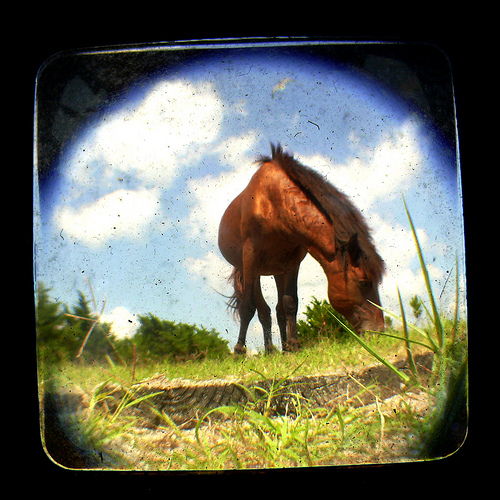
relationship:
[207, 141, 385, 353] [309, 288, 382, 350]
horse has jaw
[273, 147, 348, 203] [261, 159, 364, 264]
hair along neck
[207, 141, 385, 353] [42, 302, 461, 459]
horse standing on grass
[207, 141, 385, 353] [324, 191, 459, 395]
horse in grass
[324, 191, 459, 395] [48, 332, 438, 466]
grass in field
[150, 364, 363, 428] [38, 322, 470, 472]
wooden edging on grass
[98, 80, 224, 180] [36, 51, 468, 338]
clouds in sky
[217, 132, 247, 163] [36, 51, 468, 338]
clouds in sky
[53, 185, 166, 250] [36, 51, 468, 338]
clouds in sky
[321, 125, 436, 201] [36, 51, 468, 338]
clouds in sky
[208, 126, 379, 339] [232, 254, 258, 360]
horse has leg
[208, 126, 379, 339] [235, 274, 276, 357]
horse has leg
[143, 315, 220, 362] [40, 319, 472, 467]
green bush in field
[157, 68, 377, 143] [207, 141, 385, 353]
sky behind horse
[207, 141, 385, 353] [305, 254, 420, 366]
horse has head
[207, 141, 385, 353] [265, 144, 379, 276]
horse has mane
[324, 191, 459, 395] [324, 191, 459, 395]
grass are in grass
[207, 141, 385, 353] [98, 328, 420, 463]
horse grazing in grass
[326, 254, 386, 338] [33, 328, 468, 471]
head down to ground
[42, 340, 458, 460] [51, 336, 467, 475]
grass on ground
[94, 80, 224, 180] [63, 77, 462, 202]
clouds in sky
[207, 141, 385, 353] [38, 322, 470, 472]
horse eating grass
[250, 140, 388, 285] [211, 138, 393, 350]
mane on horse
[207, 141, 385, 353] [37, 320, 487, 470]
horse toward ground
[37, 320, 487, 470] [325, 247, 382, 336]
ground has head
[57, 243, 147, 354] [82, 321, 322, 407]
twig in grass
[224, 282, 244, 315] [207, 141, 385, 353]
hair from horse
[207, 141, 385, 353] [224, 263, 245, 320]
horse swishing tail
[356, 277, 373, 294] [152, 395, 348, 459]
eye looking at grass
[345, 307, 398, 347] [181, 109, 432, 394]
mouth of a horse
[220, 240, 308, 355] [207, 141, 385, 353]
legs of a horse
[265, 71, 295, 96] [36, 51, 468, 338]
bird flying in sky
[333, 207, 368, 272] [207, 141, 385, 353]
ear of a horse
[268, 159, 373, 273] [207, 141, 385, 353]
neck on a horse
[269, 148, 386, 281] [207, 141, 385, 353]
mane on a horse